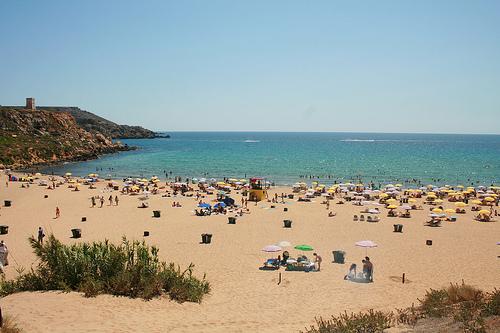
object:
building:
[25, 97, 36, 110]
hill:
[1, 96, 157, 169]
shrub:
[0, 229, 212, 305]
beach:
[0, 170, 500, 333]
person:
[313, 253, 323, 271]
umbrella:
[294, 244, 314, 255]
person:
[365, 256, 373, 282]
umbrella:
[354, 240, 378, 248]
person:
[199, 209, 205, 216]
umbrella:
[197, 203, 212, 208]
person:
[272, 255, 280, 269]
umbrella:
[260, 244, 283, 253]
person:
[301, 255, 309, 262]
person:
[482, 213, 490, 222]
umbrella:
[477, 209, 491, 214]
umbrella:
[387, 204, 399, 209]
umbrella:
[444, 208, 457, 213]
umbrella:
[432, 198, 443, 202]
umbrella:
[408, 199, 417, 202]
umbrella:
[454, 201, 466, 207]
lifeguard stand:
[248, 177, 271, 201]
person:
[114, 195, 119, 205]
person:
[108, 195, 113, 206]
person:
[99, 196, 106, 207]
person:
[91, 196, 97, 207]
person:
[55, 206, 61, 218]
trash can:
[69, 228, 83, 238]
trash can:
[153, 210, 161, 217]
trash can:
[201, 233, 213, 243]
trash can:
[284, 219, 293, 227]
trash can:
[393, 224, 403, 232]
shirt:
[56, 208, 61, 213]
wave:
[241, 138, 261, 144]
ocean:
[12, 131, 500, 193]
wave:
[338, 139, 375, 141]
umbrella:
[275, 240, 293, 247]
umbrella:
[400, 205, 412, 210]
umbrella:
[427, 213, 439, 217]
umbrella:
[483, 195, 495, 202]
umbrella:
[471, 199, 482, 204]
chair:
[353, 214, 359, 221]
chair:
[360, 214, 365, 221]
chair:
[366, 215, 373, 221]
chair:
[372, 216, 381, 222]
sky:
[0, 0, 500, 136]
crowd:
[0, 166, 500, 284]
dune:
[0, 284, 500, 333]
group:
[258, 250, 322, 272]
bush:
[395, 278, 500, 333]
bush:
[301, 307, 396, 333]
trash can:
[4, 199, 12, 206]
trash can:
[0, 225, 9, 235]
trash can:
[228, 217, 237, 225]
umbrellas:
[431, 207, 444, 212]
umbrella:
[248, 176, 264, 182]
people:
[417, 181, 422, 187]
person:
[399, 212, 411, 218]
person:
[464, 195, 470, 205]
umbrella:
[460, 190, 470, 194]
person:
[176, 201, 182, 207]